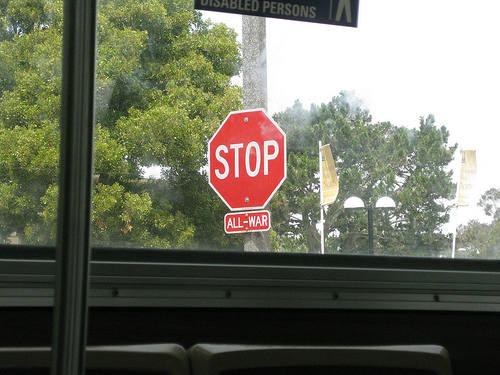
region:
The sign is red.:
[195, 100, 292, 237]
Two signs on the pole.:
[196, 20, 288, 234]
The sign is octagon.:
[196, 97, 293, 209]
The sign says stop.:
[202, 105, 289, 208]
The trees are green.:
[10, 2, 460, 252]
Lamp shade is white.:
[338, 175, 400, 214]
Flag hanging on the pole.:
[312, 130, 344, 251]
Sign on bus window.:
[191, 0, 364, 31]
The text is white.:
[192, 1, 362, 31]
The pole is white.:
[312, 127, 328, 251]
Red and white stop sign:
[203, 105, 286, 209]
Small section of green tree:
[138, 108, 187, 138]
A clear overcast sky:
[373, 51, 415, 85]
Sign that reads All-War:
[216, 213, 278, 233]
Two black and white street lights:
[345, 194, 402, 217]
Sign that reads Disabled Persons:
[203, 0, 355, 33]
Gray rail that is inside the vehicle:
[190, 270, 363, 292]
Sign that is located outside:
[456, 142, 480, 216]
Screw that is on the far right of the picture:
[430, 295, 440, 303]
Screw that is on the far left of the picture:
[105, 286, 120, 296]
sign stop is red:
[187, 97, 336, 234]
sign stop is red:
[139, 61, 372, 306]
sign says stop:
[198, 108, 285, 208]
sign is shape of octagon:
[209, 108, 289, 208]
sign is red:
[206, 112, 293, 214]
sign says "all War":
[221, 207, 272, 235]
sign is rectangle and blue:
[185, 1, 369, 30]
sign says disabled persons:
[185, 0, 368, 30]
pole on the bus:
[51, 3, 106, 373]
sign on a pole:
[231, 3, 276, 253]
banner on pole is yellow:
[319, 138, 339, 257]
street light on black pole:
[343, 189, 398, 251]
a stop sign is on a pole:
[203, 105, 287, 210]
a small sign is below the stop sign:
[218, 200, 272, 236]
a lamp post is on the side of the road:
[338, 186, 399, 253]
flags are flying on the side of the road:
[313, 137, 482, 258]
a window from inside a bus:
[7, 2, 499, 314]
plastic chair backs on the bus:
[6, 335, 458, 374]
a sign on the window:
[187, 2, 364, 27]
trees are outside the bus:
[6, 8, 497, 255]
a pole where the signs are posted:
[237, 16, 274, 246]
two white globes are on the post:
[341, 192, 398, 214]